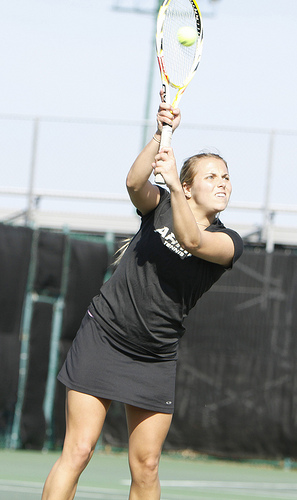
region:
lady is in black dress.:
[22, 200, 225, 418]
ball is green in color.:
[179, 22, 219, 58]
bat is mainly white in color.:
[159, 4, 197, 189]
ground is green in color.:
[180, 461, 261, 496]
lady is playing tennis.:
[121, 23, 237, 219]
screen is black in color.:
[224, 327, 294, 413]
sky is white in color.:
[18, 26, 102, 80]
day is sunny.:
[25, 125, 242, 318]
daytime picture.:
[32, 146, 261, 344]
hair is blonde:
[185, 157, 199, 179]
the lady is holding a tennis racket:
[122, 0, 234, 158]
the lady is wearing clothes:
[20, 134, 246, 491]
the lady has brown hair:
[163, 134, 249, 223]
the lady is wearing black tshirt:
[100, 164, 245, 365]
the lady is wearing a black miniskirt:
[40, 297, 215, 433]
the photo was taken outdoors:
[0, 0, 287, 489]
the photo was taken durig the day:
[0, 0, 287, 491]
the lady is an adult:
[26, 4, 210, 499]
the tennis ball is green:
[172, 19, 213, 58]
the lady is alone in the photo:
[0, 1, 285, 495]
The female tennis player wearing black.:
[55, 104, 243, 413]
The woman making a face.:
[180, 153, 231, 211]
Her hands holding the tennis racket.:
[153, 0, 203, 185]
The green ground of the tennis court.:
[186, 460, 295, 497]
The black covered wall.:
[237, 253, 295, 431]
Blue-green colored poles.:
[0, 225, 74, 449]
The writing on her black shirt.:
[154, 223, 193, 264]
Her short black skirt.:
[57, 304, 177, 413]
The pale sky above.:
[106, 21, 144, 123]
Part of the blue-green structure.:
[107, 5, 155, 84]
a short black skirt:
[56, 307, 180, 414]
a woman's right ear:
[180, 179, 194, 198]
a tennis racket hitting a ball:
[122, 0, 205, 182]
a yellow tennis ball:
[175, 20, 195, 44]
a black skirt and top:
[52, 187, 242, 414]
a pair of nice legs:
[41, 383, 176, 496]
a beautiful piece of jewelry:
[147, 131, 159, 146]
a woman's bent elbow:
[172, 220, 208, 252]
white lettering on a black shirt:
[152, 222, 193, 258]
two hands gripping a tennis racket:
[152, 100, 183, 190]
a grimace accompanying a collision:
[124, 0, 268, 303]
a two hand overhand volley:
[124, 2, 252, 260]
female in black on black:
[33, 104, 262, 494]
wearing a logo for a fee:
[144, 224, 197, 261]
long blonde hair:
[98, 220, 168, 272]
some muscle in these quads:
[38, 368, 181, 497]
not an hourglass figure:
[61, 199, 153, 376]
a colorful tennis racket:
[117, 0, 226, 188]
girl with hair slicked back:
[108, 129, 253, 267]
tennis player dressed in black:
[24, 85, 262, 466]